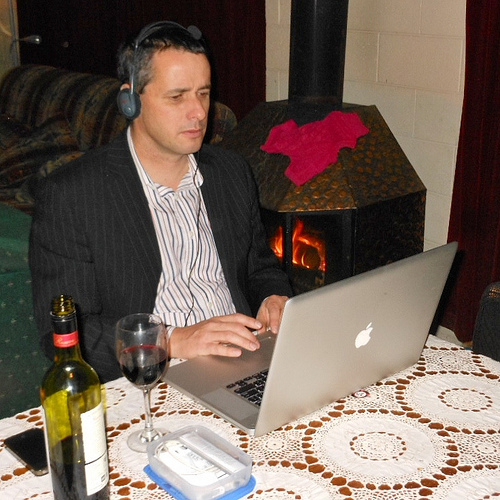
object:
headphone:
[112, 18, 207, 119]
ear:
[116, 79, 137, 111]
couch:
[109, 64, 235, 154]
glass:
[105, 322, 173, 393]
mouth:
[176, 124, 204, 138]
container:
[142, 421, 255, 497]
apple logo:
[352, 322, 378, 350]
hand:
[169, 313, 261, 356]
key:
[234, 382, 254, 394]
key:
[239, 378, 248, 386]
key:
[224, 380, 235, 388]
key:
[241, 384, 259, 397]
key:
[253, 372, 264, 383]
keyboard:
[230, 371, 262, 406]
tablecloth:
[276, 417, 494, 497]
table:
[3, 296, 498, 498]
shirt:
[122, 125, 248, 363]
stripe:
[166, 283, 186, 321]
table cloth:
[10, 350, 496, 497]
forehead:
[151, 50, 212, 89]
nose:
[186, 97, 206, 126]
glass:
[114, 311, 172, 456]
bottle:
[36, 290, 113, 499]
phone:
[3, 425, 61, 480]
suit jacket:
[30, 130, 280, 314]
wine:
[45, 429, 112, 497]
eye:
[171, 92, 183, 99]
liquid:
[117, 342, 172, 382]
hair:
[102, 26, 212, 98]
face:
[148, 52, 211, 155]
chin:
[171, 137, 211, 154]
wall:
[330, 17, 471, 194]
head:
[115, 23, 217, 148]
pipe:
[287, 7, 350, 107]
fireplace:
[234, 101, 426, 290]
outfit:
[27, 140, 291, 379]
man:
[24, 13, 299, 380]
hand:
[249, 287, 294, 343]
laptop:
[155, 234, 461, 432]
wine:
[116, 343, 169, 390]